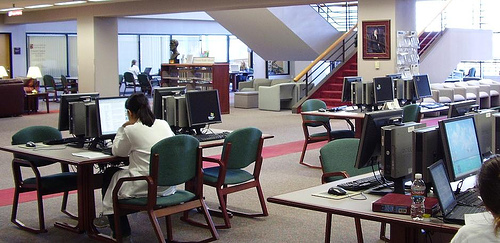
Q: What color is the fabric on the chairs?
A: Green.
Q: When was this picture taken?
A: Daytime.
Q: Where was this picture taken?
A: A library.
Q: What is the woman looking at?
A: Computer screen.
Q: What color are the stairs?
A: Red.